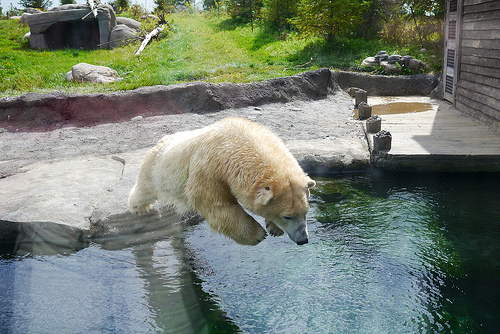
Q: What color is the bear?
A: White.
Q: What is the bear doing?
A: Jumping.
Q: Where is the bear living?
A: An enclosure.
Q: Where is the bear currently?
A: In the air.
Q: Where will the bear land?
A: In water.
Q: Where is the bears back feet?
A: On the bank.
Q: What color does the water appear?
A: Green.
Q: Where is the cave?
A: Up the hill.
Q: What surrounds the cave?
A: Grass.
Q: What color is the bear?
A: White.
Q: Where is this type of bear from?
A: Antarctica.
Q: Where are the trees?
A: Background.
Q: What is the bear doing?
A: Looking in the water.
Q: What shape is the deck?
A: Rectangular.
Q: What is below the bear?
A: Water.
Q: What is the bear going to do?
A: Jump in water.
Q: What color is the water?
A: Blue.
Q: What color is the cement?
A: White.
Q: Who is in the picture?
A: A polar bear.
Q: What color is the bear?
A: White.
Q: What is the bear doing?
A: Jumping in the water.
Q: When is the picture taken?
A: Daytime.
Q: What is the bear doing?
A: Jumping into the water.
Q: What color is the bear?
A: White.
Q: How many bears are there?
A: 1.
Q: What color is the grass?
A: Green.